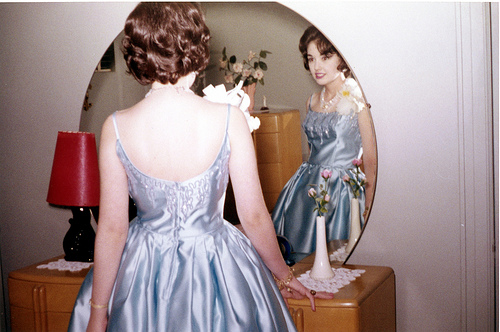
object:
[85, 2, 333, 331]
woman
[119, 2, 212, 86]
head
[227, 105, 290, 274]
arm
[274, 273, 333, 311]
hand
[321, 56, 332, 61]
eye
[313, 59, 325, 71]
nose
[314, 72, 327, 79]
mouth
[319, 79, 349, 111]
necklace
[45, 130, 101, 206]
lamp shade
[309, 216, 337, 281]
vase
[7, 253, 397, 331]
dresser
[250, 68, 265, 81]
flower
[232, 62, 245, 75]
flower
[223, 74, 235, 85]
flower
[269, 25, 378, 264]
image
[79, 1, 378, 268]
mirror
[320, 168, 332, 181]
flower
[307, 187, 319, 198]
flower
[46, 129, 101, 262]
lamp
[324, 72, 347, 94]
neck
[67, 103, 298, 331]
dress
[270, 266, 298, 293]
bracelet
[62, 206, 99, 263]
lamp base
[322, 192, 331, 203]
rose bud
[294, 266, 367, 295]
doily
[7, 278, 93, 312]
dresser drawer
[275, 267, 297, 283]
wrist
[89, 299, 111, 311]
ribbon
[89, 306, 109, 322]
wrist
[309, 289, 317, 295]
ring